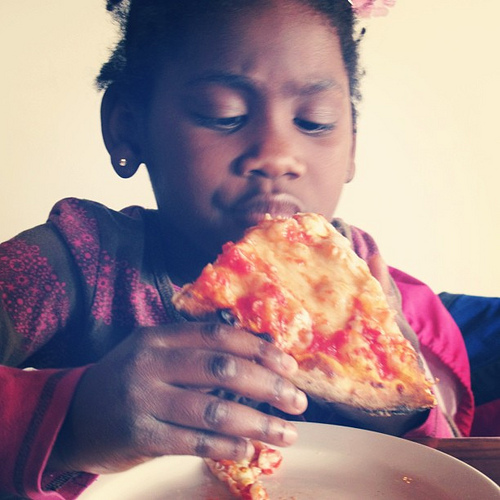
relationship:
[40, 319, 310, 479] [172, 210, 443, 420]
hand holding pizza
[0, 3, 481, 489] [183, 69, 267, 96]
child has eyebrown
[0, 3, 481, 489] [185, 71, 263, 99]
child has eyebrow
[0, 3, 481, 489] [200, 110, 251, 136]
child has eye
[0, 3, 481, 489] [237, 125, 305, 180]
child has nose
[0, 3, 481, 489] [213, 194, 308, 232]
child has lips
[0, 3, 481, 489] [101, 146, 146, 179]
child has earring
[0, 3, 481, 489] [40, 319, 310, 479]
child has hand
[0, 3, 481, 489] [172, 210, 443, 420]
child has pizza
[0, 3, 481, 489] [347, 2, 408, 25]
child has bow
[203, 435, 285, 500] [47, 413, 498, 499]
chunk on plate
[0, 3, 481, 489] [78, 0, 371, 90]
child has hair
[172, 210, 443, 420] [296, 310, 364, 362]
pizza made of tomatos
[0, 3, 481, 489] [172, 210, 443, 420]
child eating pizza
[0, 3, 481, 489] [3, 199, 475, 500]
child wearing sweater